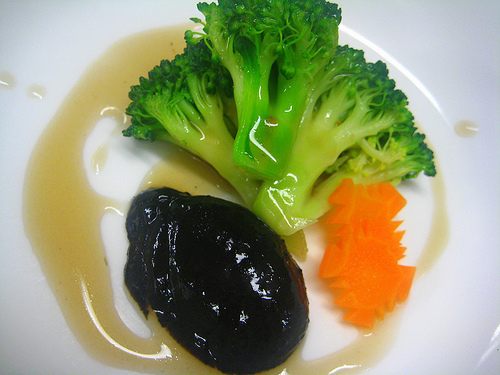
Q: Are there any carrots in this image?
A: Yes, there is a carrot.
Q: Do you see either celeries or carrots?
A: Yes, there is a carrot.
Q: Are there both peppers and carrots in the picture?
A: No, there is a carrot but no peppers.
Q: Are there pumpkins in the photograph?
A: No, there are no pumpkins.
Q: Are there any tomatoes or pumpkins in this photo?
A: No, there are no pumpkins or tomatoes.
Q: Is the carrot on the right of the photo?
A: Yes, the carrot is on the right of the image.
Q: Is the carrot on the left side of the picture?
A: No, the carrot is on the right of the image.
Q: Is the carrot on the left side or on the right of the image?
A: The carrot is on the right of the image.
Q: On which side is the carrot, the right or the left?
A: The carrot is on the right of the image.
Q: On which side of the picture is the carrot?
A: The carrot is on the right of the image.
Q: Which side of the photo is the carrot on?
A: The carrot is on the right of the image.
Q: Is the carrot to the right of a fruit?
A: Yes, the carrot is to the right of a fruit.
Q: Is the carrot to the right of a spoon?
A: No, the carrot is to the right of a fruit.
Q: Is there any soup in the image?
A: No, there is no soup.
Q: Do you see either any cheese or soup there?
A: No, there are no soup or cheese.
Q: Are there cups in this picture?
A: No, there are no cups.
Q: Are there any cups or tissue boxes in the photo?
A: No, there are no cups or tissue boxes.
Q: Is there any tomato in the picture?
A: No, there are no tomatoes.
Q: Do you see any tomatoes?
A: No, there are no tomatoes.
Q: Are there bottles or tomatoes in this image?
A: No, there are no tomatoes or bottles.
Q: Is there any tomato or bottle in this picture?
A: No, there are no tomatoes or bottles.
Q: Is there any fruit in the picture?
A: Yes, there is a fruit.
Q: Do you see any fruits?
A: Yes, there is a fruit.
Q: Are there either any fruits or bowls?
A: Yes, there is a fruit.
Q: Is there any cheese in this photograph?
A: No, there is no cheese.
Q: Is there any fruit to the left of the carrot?
A: Yes, there is a fruit to the left of the carrot.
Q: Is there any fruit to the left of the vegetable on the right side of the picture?
A: Yes, there is a fruit to the left of the carrot.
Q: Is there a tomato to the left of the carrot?
A: No, there is a fruit to the left of the carrot.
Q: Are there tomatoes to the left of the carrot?
A: No, there is a fruit to the left of the carrot.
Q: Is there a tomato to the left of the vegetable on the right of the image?
A: No, there is a fruit to the left of the carrot.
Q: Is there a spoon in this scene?
A: No, there are no spoons.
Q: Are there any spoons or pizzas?
A: No, there are no spoons or pizzas.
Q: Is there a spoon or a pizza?
A: No, there are no spoons or pizzas.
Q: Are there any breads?
A: No, there are no breads.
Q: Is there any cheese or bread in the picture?
A: No, there are no breads or cheese.